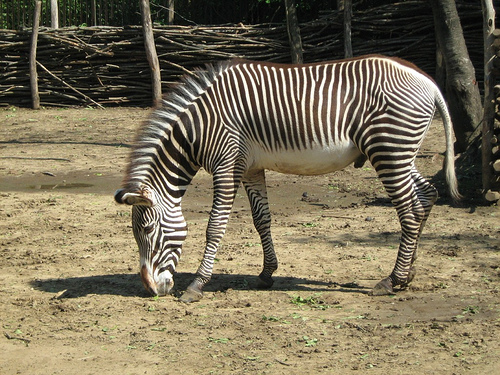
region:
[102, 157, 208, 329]
zebra sniffing the ground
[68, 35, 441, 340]
white and brown stripes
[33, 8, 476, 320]
a zebra in a zoo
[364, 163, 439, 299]
the back legs of a zebra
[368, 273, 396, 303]
the hoof of a zebra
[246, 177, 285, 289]
the leg of a zebra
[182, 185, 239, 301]
the leg of a zebra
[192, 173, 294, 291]
the front legs of a zebra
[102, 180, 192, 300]
the head of a zebra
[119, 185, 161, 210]
the ear of a zebra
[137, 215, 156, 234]
the eye of a zebra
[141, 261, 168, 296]
the nose of a zebra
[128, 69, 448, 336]
this is a zebra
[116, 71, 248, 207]
this is an animal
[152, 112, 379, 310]
these are some legs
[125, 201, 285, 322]
the legs are long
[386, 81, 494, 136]
this is a tail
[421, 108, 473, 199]
the tail is long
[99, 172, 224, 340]
this is a head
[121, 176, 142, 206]
this is an ear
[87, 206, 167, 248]
this is an eye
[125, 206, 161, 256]
the eye is black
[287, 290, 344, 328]
leaves on the ground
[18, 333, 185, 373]
dirt on the ground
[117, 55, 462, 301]
a zebra eating off the ground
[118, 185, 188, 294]
a face of the zebra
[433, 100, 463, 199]
a tail of the zebra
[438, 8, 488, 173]
the trunk of the tree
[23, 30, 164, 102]
sticks stacked up on the ground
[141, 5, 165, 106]
a stick stood up on the ground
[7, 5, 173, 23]
green trees in the background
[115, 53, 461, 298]
a black and white zebra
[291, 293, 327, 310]
small patch of grass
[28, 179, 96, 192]
Small puddle of water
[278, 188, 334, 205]
Dark brown mud puddle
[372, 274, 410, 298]
Hoof on zebra leg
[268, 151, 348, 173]
White belly of zebra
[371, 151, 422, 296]
Back legs on zebra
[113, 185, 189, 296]
Zebra with head down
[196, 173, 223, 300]
Front leg on zebra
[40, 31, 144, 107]
Fence made of wooden branches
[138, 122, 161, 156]
Striped mane on zebra